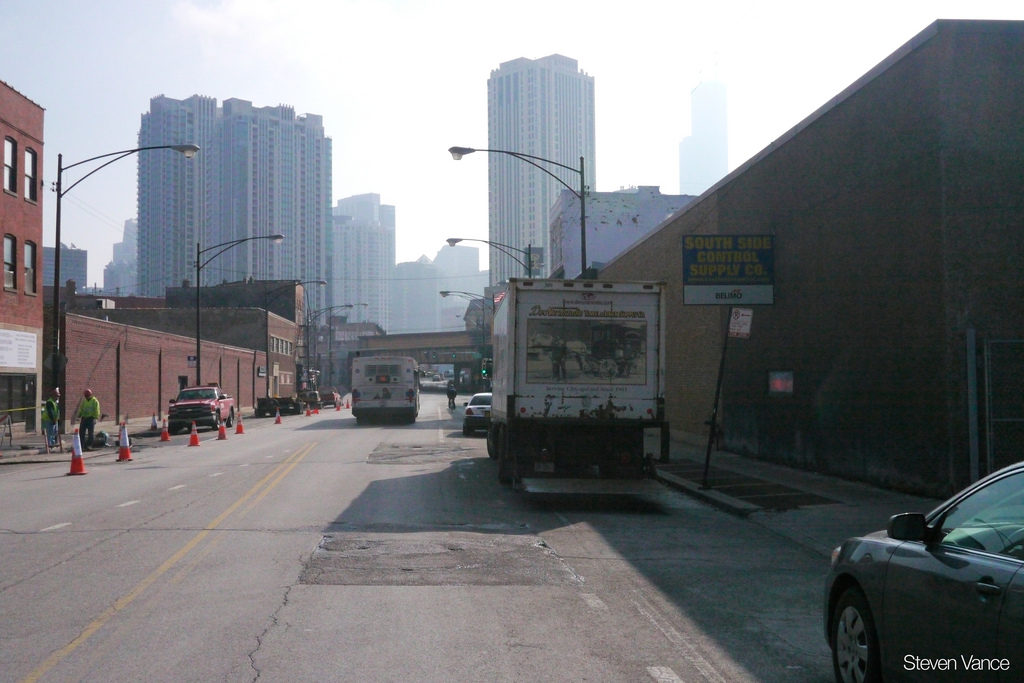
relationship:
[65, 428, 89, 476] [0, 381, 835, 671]
cone sits on street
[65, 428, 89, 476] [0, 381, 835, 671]
cone on street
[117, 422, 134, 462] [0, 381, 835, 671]
cone on street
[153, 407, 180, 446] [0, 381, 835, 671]
cone on street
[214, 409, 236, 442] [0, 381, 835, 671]
cone on street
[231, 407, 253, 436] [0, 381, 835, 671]
cone on street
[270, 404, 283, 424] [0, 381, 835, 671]
cone on street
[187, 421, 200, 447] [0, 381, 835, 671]
cone on street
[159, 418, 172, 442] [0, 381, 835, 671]
cone on street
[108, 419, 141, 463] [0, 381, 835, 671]
cone on street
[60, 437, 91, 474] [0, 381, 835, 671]
cone on street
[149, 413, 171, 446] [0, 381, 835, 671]
cone on street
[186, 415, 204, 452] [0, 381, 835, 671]
cone on street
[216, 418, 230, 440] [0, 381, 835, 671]
cone on street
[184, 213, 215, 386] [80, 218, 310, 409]
light pole behind a red truck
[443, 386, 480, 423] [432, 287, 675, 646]
car in front of a white truck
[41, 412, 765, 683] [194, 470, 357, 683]
paved city street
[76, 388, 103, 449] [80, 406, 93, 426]
man in a green shirt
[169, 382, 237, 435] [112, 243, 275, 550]
car beside light pole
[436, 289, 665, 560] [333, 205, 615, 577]
delivery truck beside signs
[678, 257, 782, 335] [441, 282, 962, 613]
sign attached to side of a building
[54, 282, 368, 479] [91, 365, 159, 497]
row of orange construction cones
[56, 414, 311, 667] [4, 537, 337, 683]
lines on pavement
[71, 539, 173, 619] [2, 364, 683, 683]
line in street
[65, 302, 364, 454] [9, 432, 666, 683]
traffic cones in street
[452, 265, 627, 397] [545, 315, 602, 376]
white delivery truck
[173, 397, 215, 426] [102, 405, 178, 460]
pick-up truck behind orange cones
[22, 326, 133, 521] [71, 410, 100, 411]
two construction workers in yellow vests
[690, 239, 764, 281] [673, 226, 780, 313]
lettering on sign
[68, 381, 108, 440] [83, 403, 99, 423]
man wearing jacket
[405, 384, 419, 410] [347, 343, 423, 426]
brake light on bus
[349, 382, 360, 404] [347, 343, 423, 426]
brake light on bus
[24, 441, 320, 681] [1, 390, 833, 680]
lines on road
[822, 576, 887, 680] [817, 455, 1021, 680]
tire on car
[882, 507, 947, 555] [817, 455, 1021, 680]
mirror on car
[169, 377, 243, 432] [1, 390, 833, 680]
car parked on side of road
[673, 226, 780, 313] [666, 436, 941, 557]
sign above sidewalk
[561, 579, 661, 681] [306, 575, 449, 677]
lines on road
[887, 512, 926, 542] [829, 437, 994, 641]
mirror on car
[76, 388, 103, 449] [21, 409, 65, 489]
man on sidewalk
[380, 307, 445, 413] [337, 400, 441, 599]
bridge over street